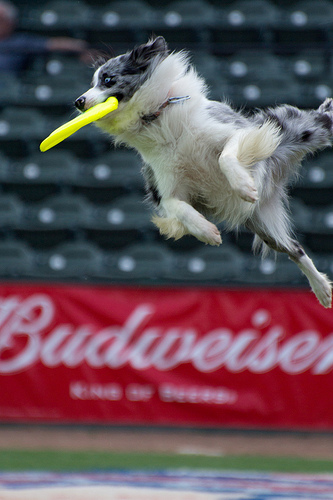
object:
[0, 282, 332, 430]
banner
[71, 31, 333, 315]
dog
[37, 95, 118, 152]
frisbee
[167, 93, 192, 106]
chain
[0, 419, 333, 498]
edge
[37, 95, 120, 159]
frisbee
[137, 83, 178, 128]
collar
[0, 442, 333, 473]
grass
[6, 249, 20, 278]
stands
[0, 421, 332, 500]
field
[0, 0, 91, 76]
person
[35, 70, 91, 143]
seats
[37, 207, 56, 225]
seat number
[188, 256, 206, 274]
seat number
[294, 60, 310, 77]
seat number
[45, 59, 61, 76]
seat number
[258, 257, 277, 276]
seat number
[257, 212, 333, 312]
legs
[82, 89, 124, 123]
mouth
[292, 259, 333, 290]
stands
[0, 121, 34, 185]
seat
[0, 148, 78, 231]
seat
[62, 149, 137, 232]
seat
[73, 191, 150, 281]
seat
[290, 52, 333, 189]
seat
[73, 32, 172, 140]
face